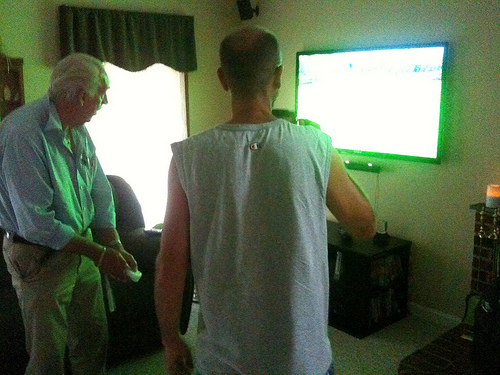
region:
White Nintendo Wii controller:
[121, 265, 143, 284]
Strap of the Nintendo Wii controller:
[97, 275, 114, 315]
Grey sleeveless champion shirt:
[171, 117, 338, 374]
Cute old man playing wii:
[1, 48, 145, 373]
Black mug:
[274, 105, 303, 124]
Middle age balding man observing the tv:
[152, 23, 377, 373]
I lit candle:
[481, 179, 498, 215]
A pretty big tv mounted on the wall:
[293, 39, 450, 164]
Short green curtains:
[55, 3, 198, 74]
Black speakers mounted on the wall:
[231, 0, 265, 20]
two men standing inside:
[46, 8, 457, 373]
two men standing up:
[2, 21, 397, 358]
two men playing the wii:
[22, 17, 397, 372]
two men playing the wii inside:
[26, 6, 340, 354]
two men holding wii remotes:
[11, 13, 336, 347]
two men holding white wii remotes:
[12, 31, 374, 366]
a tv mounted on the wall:
[282, 35, 444, 167]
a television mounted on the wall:
[272, 6, 464, 206]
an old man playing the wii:
[8, 36, 158, 369]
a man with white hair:
[12, 15, 132, 240]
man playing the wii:
[5, 51, 140, 373]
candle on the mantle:
[481, 178, 496, 204]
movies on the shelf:
[362, 256, 409, 286]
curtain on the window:
[115, 28, 197, 67]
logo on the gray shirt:
[242, 140, 264, 156]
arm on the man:
[152, 169, 192, 368]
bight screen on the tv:
[332, 53, 449, 166]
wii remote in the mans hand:
[121, 267, 144, 287]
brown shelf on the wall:
[4, 50, 24, 110]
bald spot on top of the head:
[221, 29, 267, 54]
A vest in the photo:
[192, 129, 329, 332]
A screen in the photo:
[330, 62, 431, 139]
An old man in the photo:
[0, 52, 155, 369]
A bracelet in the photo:
[95, 244, 107, 275]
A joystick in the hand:
[122, 262, 147, 288]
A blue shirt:
[2, 92, 112, 244]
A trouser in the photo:
[20, 254, 112, 366]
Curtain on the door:
[68, 18, 195, 56]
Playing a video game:
[101, 195, 147, 297]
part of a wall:
[431, 293, 433, 302]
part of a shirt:
[266, 305, 276, 320]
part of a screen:
[436, 132, 438, 137]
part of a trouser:
[76, 323, 81, 333]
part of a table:
[373, 265, 379, 297]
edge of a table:
[377, 252, 380, 259]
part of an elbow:
[368, 223, 369, 230]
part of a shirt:
[273, 247, 288, 272]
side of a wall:
[443, 215, 445, 218]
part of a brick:
[414, 355, 430, 358]